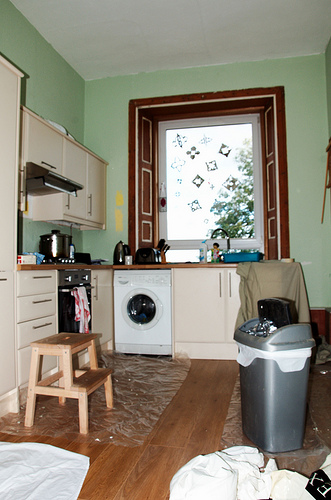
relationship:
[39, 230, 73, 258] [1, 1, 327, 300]
pot in background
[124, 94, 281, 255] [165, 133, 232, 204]
window has stickers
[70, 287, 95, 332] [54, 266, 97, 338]
towel hanging from oven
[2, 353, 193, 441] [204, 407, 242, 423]
plastic covering floor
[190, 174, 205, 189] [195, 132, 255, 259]
decals on a window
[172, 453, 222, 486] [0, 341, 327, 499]
cloth on floor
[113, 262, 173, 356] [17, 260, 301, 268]
dishwasher under counter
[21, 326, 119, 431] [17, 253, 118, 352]
step stool near counter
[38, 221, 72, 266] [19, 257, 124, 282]
cooker on counter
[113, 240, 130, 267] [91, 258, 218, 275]
iron on countertop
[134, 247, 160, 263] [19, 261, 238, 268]
toaster on counter top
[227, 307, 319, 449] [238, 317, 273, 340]
trash can filled garbage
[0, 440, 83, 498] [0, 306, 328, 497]
sheet on floor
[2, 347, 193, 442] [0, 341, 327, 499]
plastic on floor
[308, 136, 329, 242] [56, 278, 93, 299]
towel hanging from oven handle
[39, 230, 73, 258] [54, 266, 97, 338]
pot on oven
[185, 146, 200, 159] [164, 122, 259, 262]
sticker in window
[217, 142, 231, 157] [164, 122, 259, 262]
sticker in window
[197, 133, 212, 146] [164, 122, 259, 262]
sticker in window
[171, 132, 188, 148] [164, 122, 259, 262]
sticker in window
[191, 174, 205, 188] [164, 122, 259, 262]
sticker in window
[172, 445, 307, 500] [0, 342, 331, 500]
cloth protecting floor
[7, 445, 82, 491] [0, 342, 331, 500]
sheet protecting floor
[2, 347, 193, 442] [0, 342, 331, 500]
plastic protecting floor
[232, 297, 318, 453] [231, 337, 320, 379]
trash can with bag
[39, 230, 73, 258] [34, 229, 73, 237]
pot with lid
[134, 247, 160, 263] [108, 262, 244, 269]
toaster on counter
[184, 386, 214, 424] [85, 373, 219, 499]
floor made wood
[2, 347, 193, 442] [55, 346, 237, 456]
plastic on floor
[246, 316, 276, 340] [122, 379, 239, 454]
garbage on floor